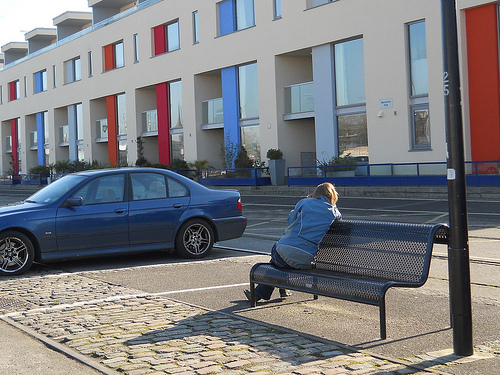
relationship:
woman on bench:
[245, 181, 342, 305] [250, 215, 453, 342]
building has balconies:
[1, 2, 499, 193] [1, 79, 315, 154]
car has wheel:
[1, 166, 247, 275] [176, 218, 217, 259]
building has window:
[1, 2, 499, 193] [14, 80, 20, 101]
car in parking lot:
[1, 166, 247, 275] [1, 200, 499, 375]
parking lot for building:
[1, 200, 499, 375] [1, 2, 499, 193]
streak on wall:
[152, 26, 172, 166] [0, 2, 498, 180]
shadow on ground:
[122, 297, 286, 351] [3, 268, 446, 372]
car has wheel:
[1, 166, 247, 275] [0, 227, 35, 275]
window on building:
[41, 69, 48, 91] [1, 2, 499, 193]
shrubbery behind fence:
[29, 164, 51, 176] [14, 163, 500, 189]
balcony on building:
[201, 95, 225, 131] [1, 2, 499, 193]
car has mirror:
[1, 166, 247, 275] [63, 195, 85, 207]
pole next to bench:
[441, 3, 475, 358] [250, 215, 453, 342]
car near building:
[1, 166, 247, 275] [1, 2, 499, 193]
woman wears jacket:
[245, 181, 342, 305] [276, 195, 345, 257]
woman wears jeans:
[245, 181, 342, 305] [255, 243, 312, 302]